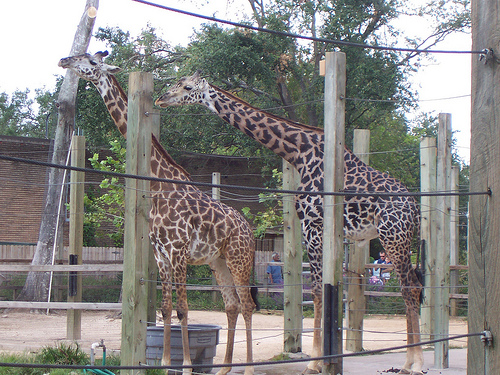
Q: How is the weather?
A: It is sunny.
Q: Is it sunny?
A: Yes, it is sunny.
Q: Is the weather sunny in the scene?
A: Yes, it is sunny.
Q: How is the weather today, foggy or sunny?
A: It is sunny.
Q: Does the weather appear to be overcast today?
A: No, it is sunny.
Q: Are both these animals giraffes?
A: Yes, all the animals are giraffes.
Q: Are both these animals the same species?
A: Yes, all the animals are giraffes.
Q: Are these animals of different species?
A: No, all the animals are giraffes.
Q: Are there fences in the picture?
A: Yes, there is a fence.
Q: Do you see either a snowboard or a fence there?
A: Yes, there is a fence.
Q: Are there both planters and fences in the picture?
A: No, there is a fence but no planters.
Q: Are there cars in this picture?
A: No, there are no cars.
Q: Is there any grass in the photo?
A: Yes, there is grass.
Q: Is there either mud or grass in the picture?
A: Yes, there is grass.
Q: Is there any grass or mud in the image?
A: Yes, there is grass.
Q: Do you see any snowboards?
A: No, there are no snowboards.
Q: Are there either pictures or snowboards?
A: No, there are no snowboards or pictures.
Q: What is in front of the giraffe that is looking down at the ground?
A: The grass is in front of the giraffe.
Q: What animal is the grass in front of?
A: The grass is in front of the giraffe.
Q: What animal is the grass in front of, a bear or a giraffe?
A: The grass is in front of a giraffe.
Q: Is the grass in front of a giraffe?
A: Yes, the grass is in front of a giraffe.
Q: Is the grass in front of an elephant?
A: No, the grass is in front of a giraffe.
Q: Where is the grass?
A: The grass is on the ground.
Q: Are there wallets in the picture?
A: No, there are no wallets.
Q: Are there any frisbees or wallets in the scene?
A: No, there are no wallets or frisbees.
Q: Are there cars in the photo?
A: No, there are no cars.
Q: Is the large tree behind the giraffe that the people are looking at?
A: Yes, the tree is behind the giraffe.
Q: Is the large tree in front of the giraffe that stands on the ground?
A: No, the tree is behind the giraffe.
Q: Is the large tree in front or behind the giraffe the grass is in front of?
A: The tree is behind the giraffe.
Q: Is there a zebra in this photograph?
A: No, there are no zebras.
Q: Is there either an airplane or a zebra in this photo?
A: No, there are no zebras or airplanes.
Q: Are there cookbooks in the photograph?
A: No, there are no cookbooks.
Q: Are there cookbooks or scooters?
A: No, there are no cookbooks or scooters.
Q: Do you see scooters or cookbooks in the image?
A: No, there are no cookbooks or scooters.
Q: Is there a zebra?
A: No, there are no zebras.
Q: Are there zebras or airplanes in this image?
A: No, there are no zebras or airplanes.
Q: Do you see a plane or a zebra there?
A: No, there are no zebras or airplanes.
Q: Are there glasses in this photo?
A: No, there are no glasses.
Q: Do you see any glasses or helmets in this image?
A: No, there are no glasses or helmets.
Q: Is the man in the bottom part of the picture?
A: Yes, the man is in the bottom of the image.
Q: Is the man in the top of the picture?
A: No, the man is in the bottom of the image.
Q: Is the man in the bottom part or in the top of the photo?
A: The man is in the bottom of the image.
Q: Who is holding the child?
A: The man is holding the child.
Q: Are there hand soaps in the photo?
A: No, there are no hand soaps.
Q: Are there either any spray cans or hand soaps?
A: No, there are no hand soaps or spray cans.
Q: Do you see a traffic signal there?
A: No, there are no traffic lights.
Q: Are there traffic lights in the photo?
A: No, there are no traffic lights.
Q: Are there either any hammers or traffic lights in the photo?
A: No, there are no traffic lights or hammers.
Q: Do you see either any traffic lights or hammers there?
A: No, there are no traffic lights or hammers.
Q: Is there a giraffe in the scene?
A: Yes, there is a giraffe.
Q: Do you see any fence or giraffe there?
A: Yes, there is a giraffe.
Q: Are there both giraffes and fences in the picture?
A: Yes, there are both a giraffe and a fence.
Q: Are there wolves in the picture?
A: No, there are no wolves.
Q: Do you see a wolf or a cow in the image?
A: No, there are no wolves or cows.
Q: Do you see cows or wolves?
A: No, there are no wolves or cows.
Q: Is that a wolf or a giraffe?
A: That is a giraffe.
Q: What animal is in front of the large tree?
A: The giraffe is in front of the tree.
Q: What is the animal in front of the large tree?
A: The animal is a giraffe.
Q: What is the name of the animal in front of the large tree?
A: The animal is a giraffe.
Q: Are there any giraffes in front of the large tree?
A: Yes, there is a giraffe in front of the tree.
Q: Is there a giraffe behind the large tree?
A: No, the giraffe is in front of the tree.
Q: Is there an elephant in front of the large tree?
A: No, there is a giraffe in front of the tree.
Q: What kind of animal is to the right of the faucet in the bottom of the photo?
A: The animal is a giraffe.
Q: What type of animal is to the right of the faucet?
A: The animal is a giraffe.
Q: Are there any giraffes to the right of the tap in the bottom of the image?
A: Yes, there is a giraffe to the right of the faucet.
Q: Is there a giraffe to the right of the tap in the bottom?
A: Yes, there is a giraffe to the right of the faucet.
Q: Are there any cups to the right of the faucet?
A: No, there is a giraffe to the right of the faucet.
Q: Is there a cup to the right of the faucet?
A: No, there is a giraffe to the right of the faucet.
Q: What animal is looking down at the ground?
A: The giraffe is looking down at the ground.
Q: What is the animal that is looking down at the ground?
A: The animal is a giraffe.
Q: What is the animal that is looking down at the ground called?
A: The animal is a giraffe.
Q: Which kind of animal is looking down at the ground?
A: The animal is a giraffe.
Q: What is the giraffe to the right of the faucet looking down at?
A: The giraffe is looking down at the ground.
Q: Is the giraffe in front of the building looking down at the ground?
A: Yes, the giraffe is looking down at the ground.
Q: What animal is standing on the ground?
A: The giraffe is standing on the ground.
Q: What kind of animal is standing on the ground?
A: The animal is a giraffe.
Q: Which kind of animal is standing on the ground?
A: The animal is a giraffe.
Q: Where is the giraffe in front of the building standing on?
A: The giraffe is standing on the ground.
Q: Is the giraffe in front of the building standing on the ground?
A: Yes, the giraffe is standing on the ground.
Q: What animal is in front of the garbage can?
A: The giraffe is in front of the garbage can.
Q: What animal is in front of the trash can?
A: The giraffe is in front of the garbage can.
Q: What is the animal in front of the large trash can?
A: The animal is a giraffe.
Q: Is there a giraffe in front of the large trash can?
A: Yes, there is a giraffe in front of the trash bin.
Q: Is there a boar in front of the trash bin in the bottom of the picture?
A: No, there is a giraffe in front of the trashcan.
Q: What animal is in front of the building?
A: The giraffe is in front of the building.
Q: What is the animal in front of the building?
A: The animal is a giraffe.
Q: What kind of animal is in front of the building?
A: The animal is a giraffe.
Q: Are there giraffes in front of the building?
A: Yes, there is a giraffe in front of the building.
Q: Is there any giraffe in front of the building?
A: Yes, there is a giraffe in front of the building.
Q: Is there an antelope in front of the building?
A: No, there is a giraffe in front of the building.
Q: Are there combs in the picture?
A: No, there are no combs.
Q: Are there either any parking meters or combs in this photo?
A: No, there are no combs or parking meters.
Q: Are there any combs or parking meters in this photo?
A: No, there are no combs or parking meters.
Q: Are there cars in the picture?
A: No, there are no cars.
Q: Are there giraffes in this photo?
A: Yes, there is a giraffe.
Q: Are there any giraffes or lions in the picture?
A: Yes, there is a giraffe.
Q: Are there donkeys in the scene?
A: No, there are no donkeys.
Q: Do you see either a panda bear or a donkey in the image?
A: No, there are no donkeys or panda bears.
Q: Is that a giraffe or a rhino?
A: That is a giraffe.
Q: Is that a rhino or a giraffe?
A: That is a giraffe.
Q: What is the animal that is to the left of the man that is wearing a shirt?
A: The animal is a giraffe.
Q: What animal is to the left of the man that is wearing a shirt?
A: The animal is a giraffe.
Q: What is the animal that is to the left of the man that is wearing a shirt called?
A: The animal is a giraffe.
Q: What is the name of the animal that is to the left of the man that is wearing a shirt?
A: The animal is a giraffe.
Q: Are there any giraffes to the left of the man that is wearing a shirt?
A: Yes, there is a giraffe to the left of the man.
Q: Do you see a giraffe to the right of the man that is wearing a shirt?
A: No, the giraffe is to the left of the man.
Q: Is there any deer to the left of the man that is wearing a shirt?
A: No, there is a giraffe to the left of the man.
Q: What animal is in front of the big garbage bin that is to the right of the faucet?
A: The giraffe is in front of the garbage can.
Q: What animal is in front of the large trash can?
A: The animal is a giraffe.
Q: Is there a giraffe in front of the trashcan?
A: Yes, there is a giraffe in front of the trashcan.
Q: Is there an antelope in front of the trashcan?
A: No, there is a giraffe in front of the trashcan.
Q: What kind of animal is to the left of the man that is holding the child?
A: The animal is a giraffe.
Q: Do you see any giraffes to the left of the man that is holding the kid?
A: Yes, there is a giraffe to the left of the man.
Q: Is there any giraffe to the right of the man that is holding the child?
A: No, the giraffe is to the left of the man.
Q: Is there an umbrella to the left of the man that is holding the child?
A: No, there is a giraffe to the left of the man.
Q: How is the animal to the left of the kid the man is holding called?
A: The animal is a giraffe.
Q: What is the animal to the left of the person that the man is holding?
A: The animal is a giraffe.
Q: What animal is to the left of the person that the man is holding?
A: The animal is a giraffe.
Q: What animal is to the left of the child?
A: The animal is a giraffe.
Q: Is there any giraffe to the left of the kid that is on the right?
A: Yes, there is a giraffe to the left of the child.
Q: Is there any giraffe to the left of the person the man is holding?
A: Yes, there is a giraffe to the left of the child.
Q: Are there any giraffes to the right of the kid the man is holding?
A: No, the giraffe is to the left of the child.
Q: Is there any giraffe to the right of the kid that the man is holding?
A: No, the giraffe is to the left of the child.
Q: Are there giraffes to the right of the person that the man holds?
A: No, the giraffe is to the left of the child.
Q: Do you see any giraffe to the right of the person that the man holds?
A: No, the giraffe is to the left of the child.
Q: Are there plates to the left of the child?
A: No, there is a giraffe to the left of the child.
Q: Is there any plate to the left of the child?
A: No, there is a giraffe to the left of the child.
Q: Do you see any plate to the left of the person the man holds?
A: No, there is a giraffe to the left of the child.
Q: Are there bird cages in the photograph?
A: No, there are no bird cages.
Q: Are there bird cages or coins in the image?
A: No, there are no bird cages or coins.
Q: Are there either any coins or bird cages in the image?
A: No, there are no bird cages or coins.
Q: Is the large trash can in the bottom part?
A: Yes, the trash can is in the bottom of the image.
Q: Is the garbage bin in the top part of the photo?
A: No, the garbage bin is in the bottom of the image.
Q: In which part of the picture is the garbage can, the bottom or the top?
A: The garbage can is in the bottom of the image.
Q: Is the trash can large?
A: Yes, the trash can is large.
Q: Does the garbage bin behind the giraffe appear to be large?
A: Yes, the trash can is large.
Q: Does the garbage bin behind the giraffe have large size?
A: Yes, the trash can is large.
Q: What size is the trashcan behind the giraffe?
A: The trash bin is large.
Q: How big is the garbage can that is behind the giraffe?
A: The trashcan is large.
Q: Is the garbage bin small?
A: No, the garbage bin is large.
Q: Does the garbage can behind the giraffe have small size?
A: No, the trash bin is large.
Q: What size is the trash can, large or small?
A: The trash can is large.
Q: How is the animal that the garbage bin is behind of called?
A: The animal is a giraffe.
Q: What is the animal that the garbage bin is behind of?
A: The animal is a giraffe.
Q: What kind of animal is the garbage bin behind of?
A: The garbage bin is behind the giraffe.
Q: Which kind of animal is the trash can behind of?
A: The garbage bin is behind the giraffe.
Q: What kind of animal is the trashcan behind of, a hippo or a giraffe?
A: The trashcan is behind a giraffe.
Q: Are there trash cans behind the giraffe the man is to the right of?
A: Yes, there is a trash can behind the giraffe.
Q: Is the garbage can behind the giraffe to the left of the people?
A: Yes, the garbage can is behind the giraffe.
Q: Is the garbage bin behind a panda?
A: No, the garbage bin is behind the giraffe.